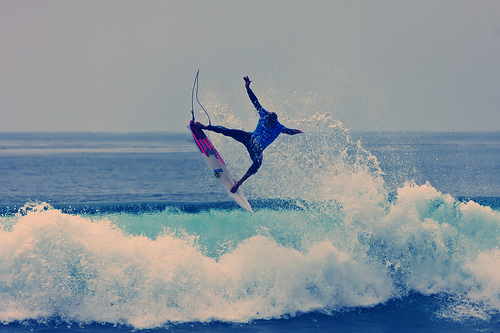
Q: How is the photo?
A: Clear.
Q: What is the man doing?
A: Surfing.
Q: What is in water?
A: Waves.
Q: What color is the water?
A: Deep blue.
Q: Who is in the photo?
A: A man.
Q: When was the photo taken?
A: Daytime.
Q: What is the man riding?
A: Surfboard.